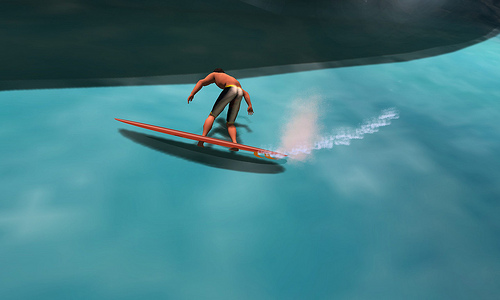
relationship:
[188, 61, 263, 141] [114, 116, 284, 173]
man on surfboard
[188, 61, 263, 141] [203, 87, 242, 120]
man wearing shorts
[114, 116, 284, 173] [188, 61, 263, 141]
surfboard under man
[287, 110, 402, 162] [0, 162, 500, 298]
spray in water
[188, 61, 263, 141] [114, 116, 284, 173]
man on skateboard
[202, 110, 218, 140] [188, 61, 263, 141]
leg on surfer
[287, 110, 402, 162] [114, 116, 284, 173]
spray from surfboard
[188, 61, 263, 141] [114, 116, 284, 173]
man riding surfboard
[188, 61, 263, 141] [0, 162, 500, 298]
man in water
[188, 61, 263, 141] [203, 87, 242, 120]
man in shorts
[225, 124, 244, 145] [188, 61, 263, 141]
leg on man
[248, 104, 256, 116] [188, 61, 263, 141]
hand on man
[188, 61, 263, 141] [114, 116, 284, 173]
man using surfboard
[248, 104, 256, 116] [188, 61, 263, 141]
hand of man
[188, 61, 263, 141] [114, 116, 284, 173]
person with surfboard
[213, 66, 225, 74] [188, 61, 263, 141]
head on man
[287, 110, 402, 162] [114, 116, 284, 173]
spray coming from surfboard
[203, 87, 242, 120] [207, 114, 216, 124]
shorts above knee